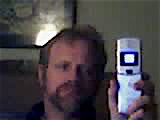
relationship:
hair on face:
[55, 85, 59, 88] [24, 15, 134, 119]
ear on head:
[31, 54, 55, 92] [19, 29, 109, 119]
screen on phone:
[119, 49, 139, 68] [109, 33, 146, 115]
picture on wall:
[0, 4, 82, 68] [2, 3, 129, 80]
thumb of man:
[95, 68, 129, 95] [24, 15, 134, 119]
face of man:
[48, 57, 94, 103] [24, 15, 134, 119]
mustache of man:
[53, 82, 81, 96] [24, 15, 134, 119]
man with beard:
[24, 15, 134, 119] [46, 93, 85, 116]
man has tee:
[24, 15, 134, 119] [24, 100, 50, 120]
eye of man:
[54, 51, 77, 74] [24, 15, 134, 119]